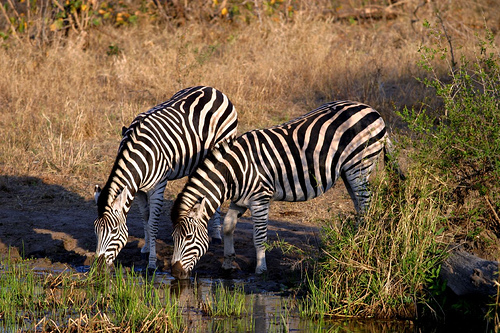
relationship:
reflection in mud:
[252, 291, 270, 331] [0, 263, 302, 331]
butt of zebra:
[336, 101, 387, 161] [171, 102, 422, 279]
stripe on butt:
[198, 161, 226, 202] [336, 101, 387, 161]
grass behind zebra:
[0, 6, 496, 193] [171, 102, 422, 279]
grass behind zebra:
[0, 6, 496, 193] [93, 85, 243, 275]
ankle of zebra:
[256, 250, 267, 277] [171, 102, 422, 279]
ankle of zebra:
[148, 245, 159, 263] [93, 85, 243, 275]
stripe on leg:
[254, 221, 267, 223] [250, 201, 270, 277]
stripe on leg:
[254, 238, 267, 244] [250, 201, 270, 277]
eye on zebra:
[185, 235, 194, 243] [171, 102, 422, 279]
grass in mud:
[0, 186, 478, 331] [0, 263, 302, 331]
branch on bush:
[430, 3, 459, 76] [386, 2, 499, 259]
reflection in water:
[318, 314, 434, 331] [0, 260, 500, 331]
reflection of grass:
[318, 314, 434, 331] [0, 186, 478, 331]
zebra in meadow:
[171, 102, 422, 279] [0, 1, 500, 331]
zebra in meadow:
[93, 85, 243, 275] [0, 1, 500, 331]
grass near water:
[0, 186, 478, 331] [0, 260, 500, 331]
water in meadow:
[0, 260, 500, 331] [0, 1, 500, 331]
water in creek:
[0, 260, 500, 331] [0, 267, 497, 331]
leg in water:
[250, 201, 270, 277] [0, 260, 500, 331]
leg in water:
[147, 192, 161, 276] [0, 260, 500, 331]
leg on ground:
[146, 192, 164, 276] [4, 188, 358, 274]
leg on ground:
[210, 214, 222, 242] [4, 188, 358, 274]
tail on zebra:
[382, 138, 405, 180] [171, 102, 422, 279]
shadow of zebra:
[1, 174, 99, 269] [93, 85, 243, 275]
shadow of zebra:
[210, 213, 327, 261] [171, 102, 422, 279]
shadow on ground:
[1, 174, 99, 269] [4, 188, 358, 274]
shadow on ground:
[210, 213, 327, 261] [4, 188, 358, 274]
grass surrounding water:
[0, 186, 478, 331] [0, 260, 500, 331]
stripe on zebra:
[303, 102, 348, 199] [171, 102, 422, 279]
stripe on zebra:
[198, 161, 226, 202] [171, 102, 422, 279]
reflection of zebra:
[252, 291, 270, 331] [171, 102, 422, 279]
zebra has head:
[171, 102, 422, 279] [170, 199, 211, 281]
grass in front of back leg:
[0, 186, 478, 331] [348, 153, 385, 213]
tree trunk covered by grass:
[436, 242, 499, 298] [0, 186, 478, 331]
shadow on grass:
[301, 66, 481, 130] [0, 6, 496, 193]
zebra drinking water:
[171, 102, 422, 279] [0, 260, 500, 331]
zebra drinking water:
[93, 85, 243, 275] [0, 260, 500, 331]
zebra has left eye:
[171, 102, 422, 279] [185, 235, 194, 243]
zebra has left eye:
[93, 85, 243, 275] [111, 229, 117, 234]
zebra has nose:
[171, 102, 422, 279] [170, 262, 185, 277]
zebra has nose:
[93, 85, 243, 275] [97, 259, 105, 267]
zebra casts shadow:
[93, 85, 243, 275] [1, 174, 99, 269]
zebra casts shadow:
[171, 102, 422, 279] [210, 213, 327, 261]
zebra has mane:
[171, 102, 422, 279] [170, 134, 239, 225]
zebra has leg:
[171, 102, 422, 279] [250, 201, 270, 277]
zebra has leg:
[93, 85, 243, 275] [147, 192, 161, 276]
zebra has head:
[93, 85, 243, 275] [91, 184, 130, 269]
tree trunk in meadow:
[436, 242, 499, 298] [0, 1, 500, 331]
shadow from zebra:
[1, 174, 99, 269] [93, 85, 243, 275]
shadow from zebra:
[210, 213, 327, 261] [171, 102, 422, 279]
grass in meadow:
[0, 6, 496, 193] [0, 1, 500, 331]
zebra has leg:
[171, 102, 422, 279] [222, 208, 242, 275]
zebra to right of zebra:
[171, 102, 422, 279] [93, 85, 243, 275]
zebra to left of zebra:
[93, 85, 243, 275] [171, 102, 422, 279]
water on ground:
[0, 260, 500, 331] [4, 188, 358, 274]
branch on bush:
[379, 103, 443, 154] [386, 2, 499, 259]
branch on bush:
[466, 15, 487, 96] [386, 2, 499, 259]